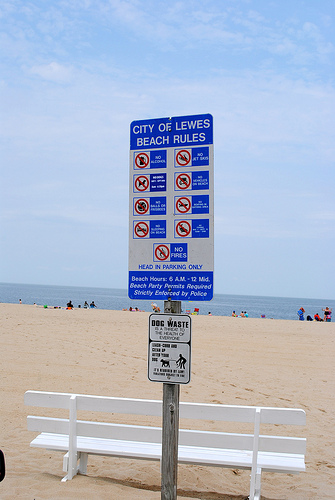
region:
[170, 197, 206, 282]
this is a beach sign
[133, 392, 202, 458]
this is a pole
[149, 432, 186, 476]
the pole is wooden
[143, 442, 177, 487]
the pole is dark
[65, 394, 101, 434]
this is a bench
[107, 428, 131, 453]
this is a bench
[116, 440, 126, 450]
the bench is white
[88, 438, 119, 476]
the bench is wooden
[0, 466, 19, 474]
this is a trashcan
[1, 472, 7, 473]
the trash is black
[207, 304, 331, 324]
some people on the beach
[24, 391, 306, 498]
a white bench on the beach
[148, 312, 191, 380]
a sign related to dogs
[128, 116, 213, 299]
a sign related to the beach rules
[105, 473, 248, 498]
the shadow of the bench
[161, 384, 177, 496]
a wooden vertical bar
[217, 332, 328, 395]
a lot of clean sand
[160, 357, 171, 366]
the figure of a dog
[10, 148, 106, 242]
a blue sky in the background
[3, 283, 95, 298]
the beach is calm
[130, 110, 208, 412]
Blue and white sign on post.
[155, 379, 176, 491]
Post attached to sign is wood.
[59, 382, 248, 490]
White bench in front of post.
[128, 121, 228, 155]
White writing on blue part of sign.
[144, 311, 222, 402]
Black writing on white sign.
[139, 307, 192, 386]
White sign attached to post.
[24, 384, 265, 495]
White bench sitting on sand.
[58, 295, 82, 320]
Person sitting on beach.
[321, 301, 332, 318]
Person standing on beach.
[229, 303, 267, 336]
People sitting on beach.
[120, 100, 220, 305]
Very long list of rules for the beach.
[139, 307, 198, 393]
Information about walking your dog on the beach.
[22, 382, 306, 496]
White bench on the sand.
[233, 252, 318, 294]
Clear blue sky in the distance.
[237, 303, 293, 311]
Beautiful blue ocean water.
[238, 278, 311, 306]
Where land and sea meet.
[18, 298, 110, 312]
People sitting on the beach.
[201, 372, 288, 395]
Tracks in the sand from people walking.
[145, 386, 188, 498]
Wooden pole where the signs are posted.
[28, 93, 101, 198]
Very light white clouds in the sky.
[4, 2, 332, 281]
white clouds in sky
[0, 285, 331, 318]
surface of calm water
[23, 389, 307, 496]
back of white bench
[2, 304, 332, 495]
sand on ocean beach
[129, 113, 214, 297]
blue and white sign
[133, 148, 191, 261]
red circles with cross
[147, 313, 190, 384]
black and white sign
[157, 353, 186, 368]
dog and human icon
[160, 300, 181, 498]
wood pole for signs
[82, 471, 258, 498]
shadow on beach sand